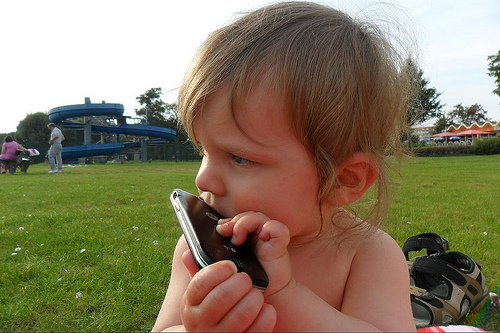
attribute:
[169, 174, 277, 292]
phone — small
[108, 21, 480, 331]
toddler — small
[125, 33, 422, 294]
boy — biting, wearing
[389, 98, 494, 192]
store — selling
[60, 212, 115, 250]
grass — green, many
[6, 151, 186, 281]
park — public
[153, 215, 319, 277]
phone — smart, cell, black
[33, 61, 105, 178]
adult — standing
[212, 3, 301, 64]
hair — brown, blond, blonde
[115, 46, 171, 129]
tree — green, tall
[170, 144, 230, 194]
nose — baby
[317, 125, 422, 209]
ear — baby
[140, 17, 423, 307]
toddler — small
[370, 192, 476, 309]
sandal — pair, large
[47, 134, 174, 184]
water — large, spiral, slide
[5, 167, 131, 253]
area — large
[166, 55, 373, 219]
kid — biting, blond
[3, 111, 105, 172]
people — talking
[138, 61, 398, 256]
child — young, chewing